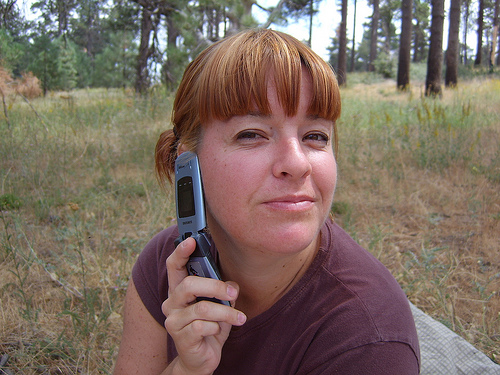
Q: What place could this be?
A: It is a park.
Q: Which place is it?
A: It is a park.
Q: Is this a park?
A: Yes, it is a park.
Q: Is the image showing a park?
A: Yes, it is showing a park.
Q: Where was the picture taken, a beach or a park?
A: It was taken at a park.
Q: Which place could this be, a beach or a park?
A: It is a park.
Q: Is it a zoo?
A: No, it is a park.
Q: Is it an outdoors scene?
A: Yes, it is outdoors.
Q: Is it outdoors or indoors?
A: It is outdoors.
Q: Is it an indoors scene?
A: No, it is outdoors.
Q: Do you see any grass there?
A: Yes, there is grass.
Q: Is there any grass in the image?
A: Yes, there is grass.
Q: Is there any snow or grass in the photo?
A: Yes, there is grass.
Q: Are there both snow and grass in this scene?
A: No, there is grass but no snow.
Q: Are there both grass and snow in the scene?
A: No, there is grass but no snow.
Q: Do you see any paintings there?
A: No, there are no paintings.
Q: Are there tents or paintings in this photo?
A: No, there are no paintings or tents.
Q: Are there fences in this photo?
A: No, there are no fences.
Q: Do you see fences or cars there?
A: No, there are no fences or cars.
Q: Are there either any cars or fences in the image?
A: No, there are no fences or cars.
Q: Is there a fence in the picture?
A: No, there are no fences.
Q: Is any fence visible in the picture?
A: No, there are no fences.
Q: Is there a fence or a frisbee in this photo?
A: No, there are no fences or frisbees.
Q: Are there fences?
A: No, there are no fences.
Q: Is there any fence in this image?
A: No, there are no fences.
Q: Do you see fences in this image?
A: No, there are no fences.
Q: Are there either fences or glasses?
A: No, there are no fences or glasses.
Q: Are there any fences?
A: No, there are no fences.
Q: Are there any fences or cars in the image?
A: No, there are no fences or cars.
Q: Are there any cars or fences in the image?
A: No, there are no fences or cars.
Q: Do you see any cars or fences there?
A: No, there are no fences or cars.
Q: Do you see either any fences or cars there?
A: No, there are no fences or cars.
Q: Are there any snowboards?
A: No, there are no snowboards.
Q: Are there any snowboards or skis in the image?
A: No, there are no snowboards or skis.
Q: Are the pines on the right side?
A: Yes, the pines are on the right of the image.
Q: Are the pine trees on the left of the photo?
A: No, the pine trees are on the right of the image.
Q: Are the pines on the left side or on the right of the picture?
A: The pines are on the right of the image.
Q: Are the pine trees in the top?
A: Yes, the pine trees are in the top of the image.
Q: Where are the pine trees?
A: The pine trees are in the forest.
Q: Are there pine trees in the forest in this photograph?
A: Yes, there are pine trees in the forest.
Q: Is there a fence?
A: No, there are no fences.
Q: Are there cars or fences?
A: No, there are no fences or cars.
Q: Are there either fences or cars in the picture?
A: No, there are no fences or cars.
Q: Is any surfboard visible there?
A: No, there are no surfboards.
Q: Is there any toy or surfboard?
A: No, there are no surfboards or toys.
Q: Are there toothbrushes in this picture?
A: No, there are no toothbrushes.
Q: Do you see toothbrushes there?
A: No, there are no toothbrushes.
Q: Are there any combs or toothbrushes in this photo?
A: No, there are no toothbrushes or combs.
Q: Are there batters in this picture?
A: No, there are no batters.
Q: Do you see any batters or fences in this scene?
A: No, there are no batters or fences.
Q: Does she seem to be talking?
A: Yes, the girl is talking.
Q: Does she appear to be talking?
A: Yes, the girl is talking.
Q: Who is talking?
A: The girl is talking.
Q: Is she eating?
A: No, the girl is talking.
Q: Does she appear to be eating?
A: No, the girl is talking.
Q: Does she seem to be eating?
A: No, the girl is talking.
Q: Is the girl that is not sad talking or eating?
A: The girl is talking.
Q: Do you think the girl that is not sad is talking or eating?
A: The girl is talking.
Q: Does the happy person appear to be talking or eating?
A: The girl is talking.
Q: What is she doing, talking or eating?
A: The girl is talking.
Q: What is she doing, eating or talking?
A: The girl is talking.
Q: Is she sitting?
A: Yes, the girl is sitting.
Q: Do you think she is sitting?
A: Yes, the girl is sitting.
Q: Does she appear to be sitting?
A: Yes, the girl is sitting.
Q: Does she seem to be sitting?
A: Yes, the girl is sitting.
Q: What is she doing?
A: The girl is sitting.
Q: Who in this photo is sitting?
A: The girl is sitting.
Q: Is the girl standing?
A: No, the girl is sitting.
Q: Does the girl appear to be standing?
A: No, the girl is sitting.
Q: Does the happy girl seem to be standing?
A: No, the girl is sitting.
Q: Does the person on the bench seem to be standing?
A: No, the girl is sitting.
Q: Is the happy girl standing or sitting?
A: The girl is sitting.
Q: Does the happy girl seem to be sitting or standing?
A: The girl is sitting.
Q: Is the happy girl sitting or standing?
A: The girl is sitting.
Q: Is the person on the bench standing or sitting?
A: The girl is sitting.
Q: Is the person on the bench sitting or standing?
A: The girl is sitting.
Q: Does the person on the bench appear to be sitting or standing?
A: The girl is sitting.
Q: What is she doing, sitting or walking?
A: The girl is sitting.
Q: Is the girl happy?
A: Yes, the girl is happy.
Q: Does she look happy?
A: Yes, the girl is happy.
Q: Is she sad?
A: No, the girl is happy.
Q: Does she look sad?
A: No, the girl is happy.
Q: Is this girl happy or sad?
A: The girl is happy.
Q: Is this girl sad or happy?
A: The girl is happy.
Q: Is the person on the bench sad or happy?
A: The girl is happy.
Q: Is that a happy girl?
A: Yes, that is a happy girl.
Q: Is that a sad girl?
A: No, that is a happy girl.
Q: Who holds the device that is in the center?
A: The girl holds the mobile phone.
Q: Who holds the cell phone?
A: The girl holds the mobile phone.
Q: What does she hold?
A: The girl holds the cell phone.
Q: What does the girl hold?
A: The girl holds the cell phone.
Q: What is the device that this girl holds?
A: The device is a cell phone.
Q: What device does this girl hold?
A: The girl holds the cell phone.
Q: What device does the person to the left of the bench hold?
A: The girl holds the cell phone.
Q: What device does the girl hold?
A: The girl holds the cell phone.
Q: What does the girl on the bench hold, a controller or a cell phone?
A: The girl holds a cell phone.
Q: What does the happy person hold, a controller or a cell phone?
A: The girl holds a cell phone.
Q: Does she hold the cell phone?
A: Yes, the girl holds the cell phone.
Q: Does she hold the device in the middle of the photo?
A: Yes, the girl holds the cell phone.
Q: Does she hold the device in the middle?
A: Yes, the girl holds the cell phone.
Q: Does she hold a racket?
A: No, the girl holds the cell phone.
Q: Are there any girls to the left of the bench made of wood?
A: Yes, there is a girl to the left of the bench.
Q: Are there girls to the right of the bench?
A: No, the girl is to the left of the bench.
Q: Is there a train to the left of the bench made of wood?
A: No, there is a girl to the left of the bench.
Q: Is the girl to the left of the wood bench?
A: Yes, the girl is to the left of the bench.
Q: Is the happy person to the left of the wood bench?
A: Yes, the girl is to the left of the bench.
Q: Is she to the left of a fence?
A: No, the girl is to the left of the bench.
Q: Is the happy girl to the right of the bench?
A: No, the girl is to the left of the bench.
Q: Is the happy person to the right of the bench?
A: No, the girl is to the left of the bench.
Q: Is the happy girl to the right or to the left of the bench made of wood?
A: The girl is to the left of the bench.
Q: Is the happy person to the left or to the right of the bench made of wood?
A: The girl is to the left of the bench.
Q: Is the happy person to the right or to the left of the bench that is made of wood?
A: The girl is to the left of the bench.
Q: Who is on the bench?
A: The girl is on the bench.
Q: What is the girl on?
A: The girl is on the bench.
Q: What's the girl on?
A: The girl is on the bench.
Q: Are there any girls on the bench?
A: Yes, there is a girl on the bench.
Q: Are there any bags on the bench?
A: No, there is a girl on the bench.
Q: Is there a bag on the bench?
A: No, there is a girl on the bench.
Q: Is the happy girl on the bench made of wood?
A: Yes, the girl is on the bench.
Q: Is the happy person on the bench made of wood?
A: Yes, the girl is on the bench.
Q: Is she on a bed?
A: No, the girl is on the bench.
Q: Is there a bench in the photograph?
A: Yes, there is a bench.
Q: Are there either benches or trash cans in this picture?
A: Yes, there is a bench.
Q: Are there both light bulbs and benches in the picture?
A: No, there is a bench but no light bulbs.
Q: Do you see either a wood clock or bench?
A: Yes, there is a wood bench.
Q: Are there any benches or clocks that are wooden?
A: Yes, the bench is wooden.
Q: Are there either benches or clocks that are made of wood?
A: Yes, the bench is made of wood.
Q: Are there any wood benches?
A: Yes, there is a wood bench.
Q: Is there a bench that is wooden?
A: Yes, there is a bench that is wooden.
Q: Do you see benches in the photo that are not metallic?
A: Yes, there is a wooden bench.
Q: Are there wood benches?
A: Yes, there is a bench that is made of wood.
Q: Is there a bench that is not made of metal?
A: Yes, there is a bench that is made of wood.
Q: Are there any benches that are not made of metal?
A: Yes, there is a bench that is made of wood.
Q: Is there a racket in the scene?
A: No, there are no rackets.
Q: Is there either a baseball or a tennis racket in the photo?
A: No, there are no rackets or baseballs.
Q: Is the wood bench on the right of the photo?
A: Yes, the bench is on the right of the image.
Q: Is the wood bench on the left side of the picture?
A: No, the bench is on the right of the image.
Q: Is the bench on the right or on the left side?
A: The bench is on the right of the image.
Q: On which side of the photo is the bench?
A: The bench is on the right of the image.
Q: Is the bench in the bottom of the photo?
A: Yes, the bench is in the bottom of the image.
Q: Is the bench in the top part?
A: No, the bench is in the bottom of the image.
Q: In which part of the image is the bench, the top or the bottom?
A: The bench is in the bottom of the image.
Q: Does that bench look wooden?
A: Yes, the bench is wooden.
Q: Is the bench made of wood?
A: Yes, the bench is made of wood.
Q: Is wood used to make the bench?
A: Yes, the bench is made of wood.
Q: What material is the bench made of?
A: The bench is made of wood.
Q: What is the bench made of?
A: The bench is made of wood.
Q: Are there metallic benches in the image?
A: No, there is a bench but it is wooden.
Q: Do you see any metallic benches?
A: No, there is a bench but it is wooden.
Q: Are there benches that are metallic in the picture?
A: No, there is a bench but it is wooden.